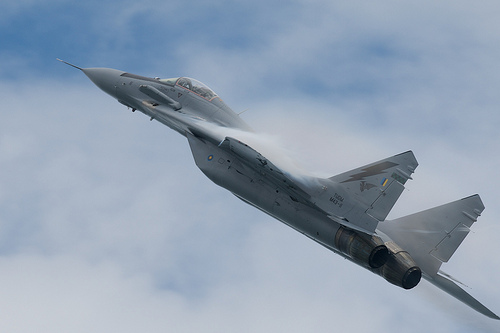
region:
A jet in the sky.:
[121, 15, 449, 317]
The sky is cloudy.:
[53, 181, 181, 304]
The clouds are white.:
[43, 203, 232, 313]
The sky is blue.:
[21, 188, 238, 326]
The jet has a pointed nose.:
[38, 44, 111, 93]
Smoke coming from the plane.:
[166, 88, 307, 157]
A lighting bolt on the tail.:
[338, 146, 398, 196]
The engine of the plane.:
[338, 228, 430, 286]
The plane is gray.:
[107, 68, 441, 273]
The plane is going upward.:
[131, 70, 454, 324]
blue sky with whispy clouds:
[0, 1, 101, 54]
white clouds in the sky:
[0, 210, 251, 330]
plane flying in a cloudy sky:
[53, 56, 499, 324]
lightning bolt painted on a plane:
[337, 160, 399, 181]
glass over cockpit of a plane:
[159, 75, 217, 97]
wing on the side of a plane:
[216, 134, 317, 206]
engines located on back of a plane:
[339, 230, 432, 290]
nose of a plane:
[54, 53, 128, 92]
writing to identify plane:
[326, 189, 347, 211]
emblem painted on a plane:
[206, 154, 214, 161]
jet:
[0, 52, 316, 283]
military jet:
[62, 37, 474, 295]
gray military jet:
[71, 48, 466, 305]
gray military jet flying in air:
[69, 61, 477, 297]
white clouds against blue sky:
[5, 15, 65, 106]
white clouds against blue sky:
[19, 82, 78, 160]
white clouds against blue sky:
[21, 168, 154, 253]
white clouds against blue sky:
[113, 223, 242, 301]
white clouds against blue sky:
[128, 12, 326, 66]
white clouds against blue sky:
[343, 25, 460, 123]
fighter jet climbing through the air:
[55, 40, 495, 325]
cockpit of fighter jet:
[150, 70, 252, 115]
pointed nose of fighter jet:
[47, 53, 79, 78]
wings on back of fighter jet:
[323, 133, 495, 310]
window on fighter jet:
[156, 65, 216, 102]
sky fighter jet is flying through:
[17, 13, 475, 323]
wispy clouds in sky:
[22, 18, 471, 322]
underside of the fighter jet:
[180, 145, 335, 244]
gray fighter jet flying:
[62, 40, 492, 313]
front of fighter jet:
[75, 51, 233, 133]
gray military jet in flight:
[83, 38, 447, 298]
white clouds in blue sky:
[17, 14, 58, 99]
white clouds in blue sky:
[19, 82, 82, 153]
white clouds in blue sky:
[24, 141, 92, 224]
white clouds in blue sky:
[29, 235, 122, 303]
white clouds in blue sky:
[142, 244, 229, 285]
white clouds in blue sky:
[107, 141, 172, 222]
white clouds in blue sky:
[137, 11, 298, 64]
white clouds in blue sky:
[278, 7, 484, 96]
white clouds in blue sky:
[285, 71, 369, 134]